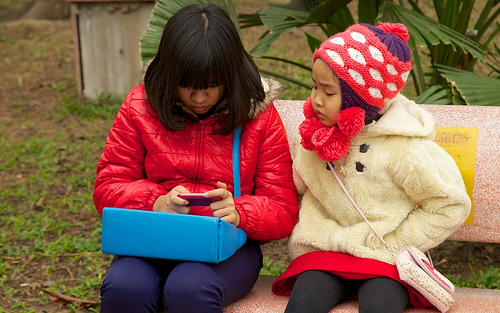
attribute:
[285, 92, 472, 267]
jacket — white, furry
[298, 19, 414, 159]
hat — woven, large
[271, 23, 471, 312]
girl — little, knitted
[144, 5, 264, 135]
hair — falling forward, dark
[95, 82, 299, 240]
jacket — red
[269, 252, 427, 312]
skirt — red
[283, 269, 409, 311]
leggings — black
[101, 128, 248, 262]
purse — blue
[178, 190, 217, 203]
cellphone — pink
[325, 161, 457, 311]
purse — tan, pink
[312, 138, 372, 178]
buttons — black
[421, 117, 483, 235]
sign — yellow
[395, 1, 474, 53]
leaves — green, large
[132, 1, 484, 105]
plant — green, large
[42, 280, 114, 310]
leaf — brown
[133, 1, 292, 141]
hair — brown, long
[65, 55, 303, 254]
jacket — red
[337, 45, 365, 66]
dot — white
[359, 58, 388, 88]
dot — white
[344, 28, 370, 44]
dot — white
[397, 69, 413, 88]
dot — white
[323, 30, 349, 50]
dot — white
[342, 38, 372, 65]
dot — white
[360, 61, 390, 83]
dot — white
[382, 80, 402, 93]
dot — white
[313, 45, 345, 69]
dot — white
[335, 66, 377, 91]
dot — white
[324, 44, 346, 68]
polka dot — white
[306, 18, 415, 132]
hat — red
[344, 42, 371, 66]
polka dot — white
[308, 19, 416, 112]
hat — red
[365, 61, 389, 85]
polka dot — white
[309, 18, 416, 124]
hat — red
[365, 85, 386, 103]
polka dot — white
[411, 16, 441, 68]
leaves — green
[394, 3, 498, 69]
leaves — green